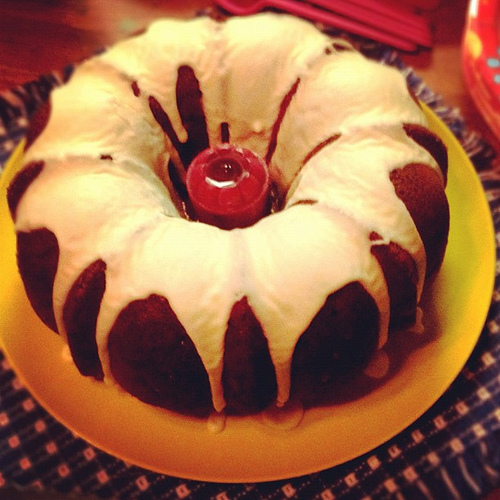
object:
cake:
[6, 12, 451, 434]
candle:
[186, 143, 273, 232]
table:
[0, 0, 500, 492]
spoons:
[211, 0, 433, 51]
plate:
[0, 98, 496, 482]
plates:
[462, 0, 500, 139]